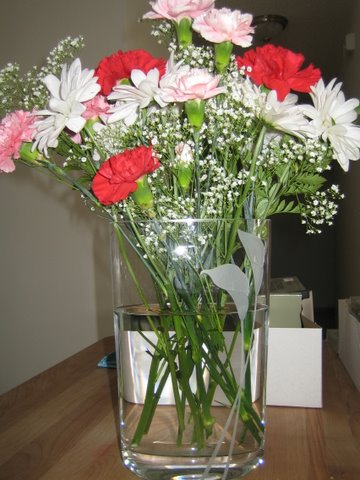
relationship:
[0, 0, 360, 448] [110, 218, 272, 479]
bouqet in a vase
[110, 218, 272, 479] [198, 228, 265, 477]
vase has a design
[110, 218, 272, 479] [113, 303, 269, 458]
vase has water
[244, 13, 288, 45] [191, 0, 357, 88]
light on ceiling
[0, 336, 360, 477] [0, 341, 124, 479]
desk has lines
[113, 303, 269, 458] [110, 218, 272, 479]
water in vase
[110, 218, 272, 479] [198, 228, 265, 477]
vase has etching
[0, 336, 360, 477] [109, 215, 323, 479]
wood has items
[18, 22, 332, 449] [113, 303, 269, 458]
stems are in water